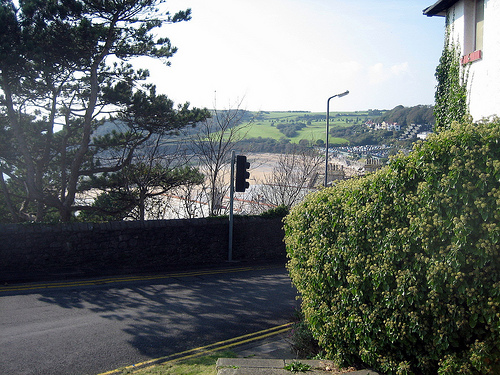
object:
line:
[133, 322, 300, 374]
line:
[91, 321, 297, 375]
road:
[0, 269, 307, 372]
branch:
[77, 160, 204, 224]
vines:
[433, 1, 472, 124]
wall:
[447, 2, 499, 123]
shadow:
[43, 269, 310, 360]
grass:
[194, 112, 367, 146]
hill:
[146, 112, 433, 152]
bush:
[281, 119, 497, 374]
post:
[325, 87, 346, 187]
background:
[0, 0, 499, 374]